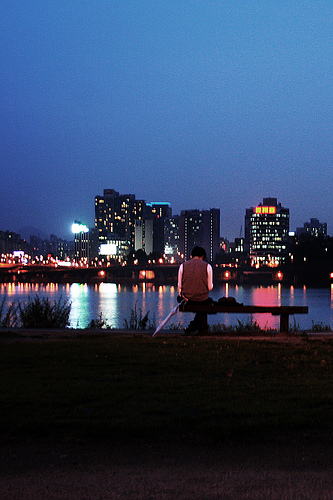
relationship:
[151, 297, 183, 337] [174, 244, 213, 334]
toy sword near boy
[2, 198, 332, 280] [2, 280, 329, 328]
lights has reflection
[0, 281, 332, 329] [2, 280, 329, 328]
water has reflection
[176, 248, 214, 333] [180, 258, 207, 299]
boy wears sweater vest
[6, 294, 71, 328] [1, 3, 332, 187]
foliage in moonlight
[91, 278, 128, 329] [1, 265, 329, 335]
line on water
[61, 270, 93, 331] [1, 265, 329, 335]
line on water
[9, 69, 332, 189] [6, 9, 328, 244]
sky in background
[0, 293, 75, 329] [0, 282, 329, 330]
shrubs growing by river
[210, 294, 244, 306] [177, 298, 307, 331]
clothing on bench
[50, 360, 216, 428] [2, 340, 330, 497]
grass on field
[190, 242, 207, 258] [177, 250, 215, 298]
head of man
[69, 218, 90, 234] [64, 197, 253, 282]
sign on building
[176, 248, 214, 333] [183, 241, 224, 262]
boy has head